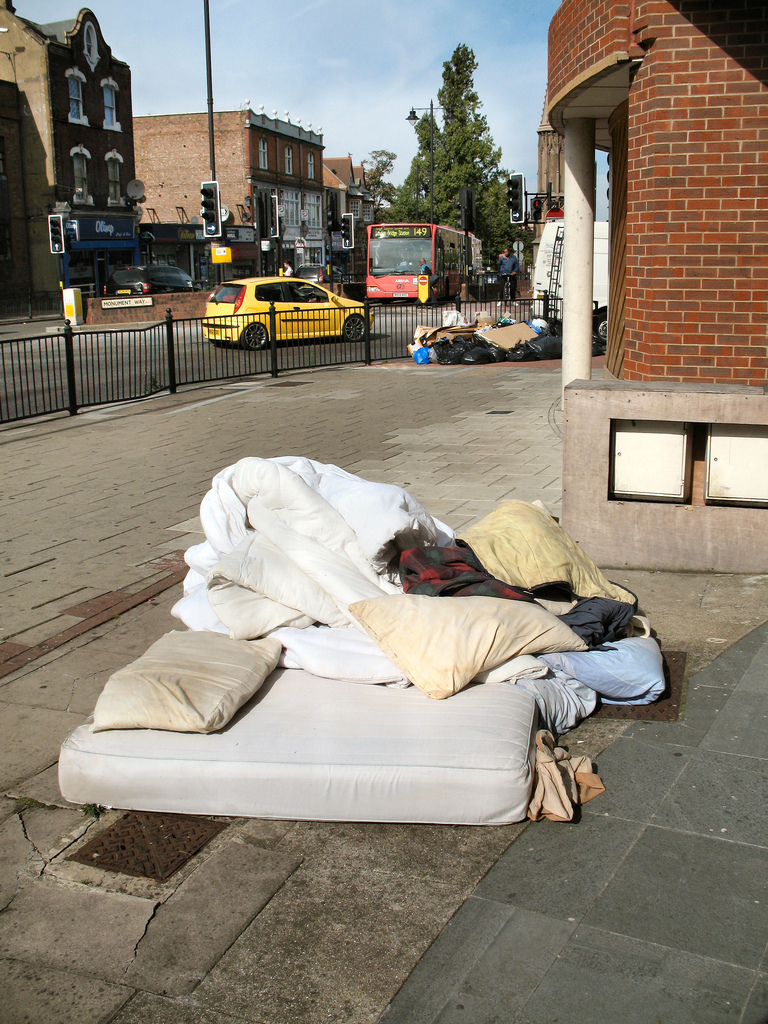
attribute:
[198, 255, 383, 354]
car — YELLOW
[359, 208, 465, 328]
bus — RED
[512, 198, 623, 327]
van — WHITE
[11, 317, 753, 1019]
sidewalk — brick , gray , Broken, concrete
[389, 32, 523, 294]
tree — TALL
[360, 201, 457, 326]
bus front — red, yellow 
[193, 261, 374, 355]
car — yellow , small 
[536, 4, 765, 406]
building — red, brick , well constructed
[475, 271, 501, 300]
shirt — blue 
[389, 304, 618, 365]
trash — pile 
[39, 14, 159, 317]
store front — blue 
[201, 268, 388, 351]
car — small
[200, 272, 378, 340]
car — small, yellow 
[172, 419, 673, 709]
blankets — pile 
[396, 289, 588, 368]
trash bags — pile 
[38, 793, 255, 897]
sewer drain — rusty 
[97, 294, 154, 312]
sign — white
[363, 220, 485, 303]
bus — large, red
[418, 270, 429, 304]
sign — red, yellow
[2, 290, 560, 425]
fence — black, iron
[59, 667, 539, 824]
mattress — old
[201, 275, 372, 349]
cab — yellow